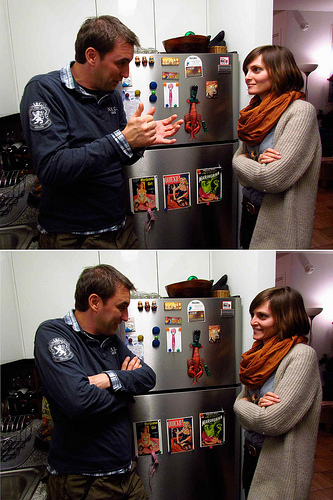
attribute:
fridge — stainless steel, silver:
[128, 50, 244, 248]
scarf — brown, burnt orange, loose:
[233, 90, 305, 141]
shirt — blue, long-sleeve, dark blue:
[21, 63, 129, 230]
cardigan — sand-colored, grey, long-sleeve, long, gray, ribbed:
[240, 97, 320, 247]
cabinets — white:
[3, 4, 274, 119]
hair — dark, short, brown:
[240, 47, 303, 92]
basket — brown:
[163, 34, 212, 52]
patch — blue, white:
[27, 101, 52, 130]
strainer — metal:
[1, 172, 28, 195]